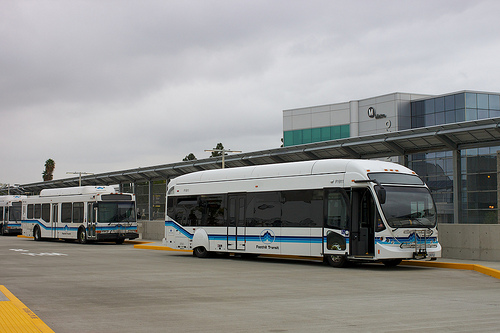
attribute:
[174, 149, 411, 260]
bus — large, white, blue, sitting, parked, striped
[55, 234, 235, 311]
road — grey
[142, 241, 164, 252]
sidewalk — paved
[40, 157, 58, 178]
tree — large, green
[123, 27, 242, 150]
sky — cloudy, overcast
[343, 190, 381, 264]
door — open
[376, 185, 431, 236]
windshield — black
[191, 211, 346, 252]
stripe — blue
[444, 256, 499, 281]
curb — yellow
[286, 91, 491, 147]
building — green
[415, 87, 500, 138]
windows — reflective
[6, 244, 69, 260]
pavement — white, grey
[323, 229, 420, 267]
wheels — black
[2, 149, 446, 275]
buses — white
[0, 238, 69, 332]
road — yellow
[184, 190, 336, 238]
windows — tinted, large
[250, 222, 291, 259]
logo — blue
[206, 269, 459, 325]
concrete — grey